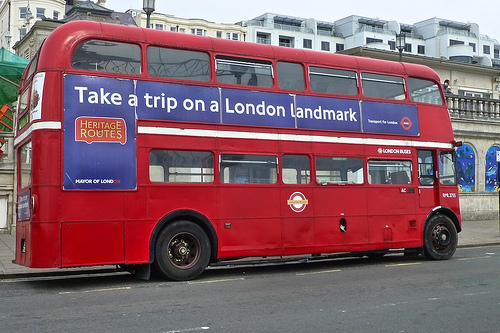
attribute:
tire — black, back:
[148, 224, 217, 278]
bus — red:
[9, 21, 486, 288]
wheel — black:
[419, 212, 456, 262]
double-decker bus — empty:
[6, 19, 462, 278]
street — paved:
[0, 239, 498, 331]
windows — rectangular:
[143, 140, 418, 190]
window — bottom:
[144, 153, 217, 184]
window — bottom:
[215, 155, 285, 185]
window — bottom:
[278, 151, 313, 183]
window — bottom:
[317, 149, 365, 187]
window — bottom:
[370, 161, 410, 188]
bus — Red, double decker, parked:
[16, 22, 463, 274]